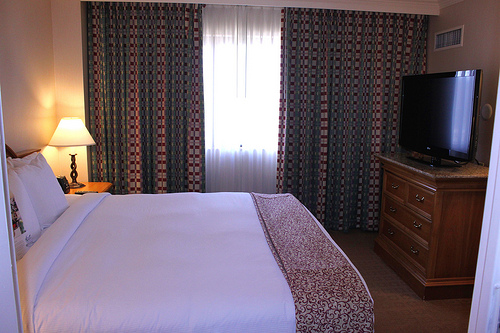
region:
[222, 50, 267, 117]
part of a light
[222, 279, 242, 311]
par of a bed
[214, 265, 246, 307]
part of a sheet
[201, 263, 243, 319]
part of a sheet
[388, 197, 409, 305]
part of a board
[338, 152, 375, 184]
part of a curtain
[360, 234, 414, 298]
part of a floor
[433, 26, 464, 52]
a white vent on the wall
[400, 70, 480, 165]
a black flat screen TV on a dresser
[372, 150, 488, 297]
a wooden dresser in a bedroom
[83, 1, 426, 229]
green, red and white drapes on the window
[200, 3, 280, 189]
white drapes on the window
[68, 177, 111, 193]
a wooden night stand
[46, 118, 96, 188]
a lamp on a night stand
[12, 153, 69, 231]
a white pillow on a bed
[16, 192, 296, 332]
white bedding on a bed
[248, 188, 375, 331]
a white and red blanket on the foot of the bed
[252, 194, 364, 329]
blanket draped across foot of bed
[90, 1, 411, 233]
long patterned curtains on windows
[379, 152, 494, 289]
dresser tv is sitting on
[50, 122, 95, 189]
lamp sitting on the night stand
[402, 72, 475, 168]
black flatscreen television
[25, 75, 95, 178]
light from lamp on the walls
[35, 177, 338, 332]
white blanket on bed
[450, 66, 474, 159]
reflection on black flatscreen tv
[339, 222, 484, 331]
brown flooring of bedroom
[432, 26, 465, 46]
white vent on the wall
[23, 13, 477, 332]
the scene is in a bedroom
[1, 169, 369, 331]
the bed is well spread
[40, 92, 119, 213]
the lamp is on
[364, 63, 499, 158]
the television is off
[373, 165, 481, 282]
the drawer is wooden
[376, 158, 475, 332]
the drawers are brown in colour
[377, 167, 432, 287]
the drawers are closed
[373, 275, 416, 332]
the floor is tiled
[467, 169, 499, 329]
the curtain is white in colour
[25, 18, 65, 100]
the wall is brown in colour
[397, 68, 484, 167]
An HD television set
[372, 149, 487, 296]
An old fashioned brown dresser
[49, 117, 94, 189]
A lamp in the corner of a room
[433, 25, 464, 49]
A vent on a wall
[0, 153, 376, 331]
A mattress with blankets over it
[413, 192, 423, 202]
A drawer handle on a dresser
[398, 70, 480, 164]
A black television set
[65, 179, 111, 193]
A wooden table in a corner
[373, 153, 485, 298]
A wooden dresser with detail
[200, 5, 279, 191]
The opening of a window with curtains in front